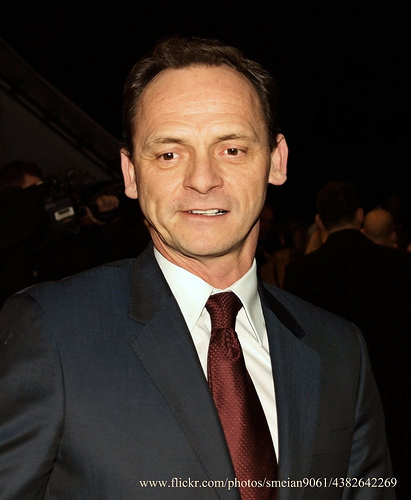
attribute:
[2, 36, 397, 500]
man — standing, smiling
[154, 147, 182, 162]
eye — brown, open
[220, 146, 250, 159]
eye — brown, open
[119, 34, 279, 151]
hair — dark, brown, short, groomed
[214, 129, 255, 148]
eyebrow — brown, arched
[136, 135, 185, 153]
eyebrow — brown, arched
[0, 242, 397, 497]
jacket — blue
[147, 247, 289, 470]
shirt — white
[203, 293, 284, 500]
necktie — brown